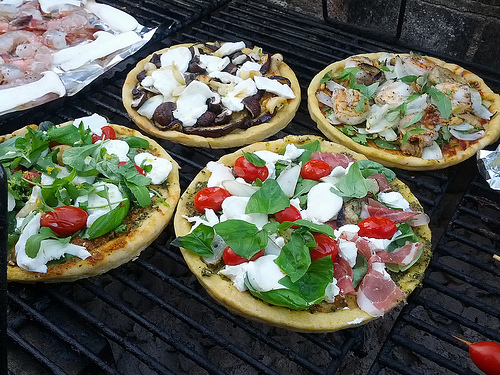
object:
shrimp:
[40, 29, 71, 50]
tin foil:
[0, 0, 159, 117]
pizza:
[306, 51, 500, 173]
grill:
[0, 0, 500, 375]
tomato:
[194, 186, 234, 214]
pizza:
[173, 134, 433, 334]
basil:
[213, 218, 270, 260]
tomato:
[234, 155, 270, 184]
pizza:
[121, 41, 303, 149]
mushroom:
[153, 101, 178, 126]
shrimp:
[331, 87, 370, 126]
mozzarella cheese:
[305, 181, 345, 223]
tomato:
[356, 216, 398, 240]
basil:
[245, 178, 291, 214]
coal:
[418, 286, 465, 325]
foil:
[475, 142, 500, 191]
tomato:
[300, 159, 331, 181]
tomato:
[274, 203, 303, 229]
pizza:
[0, 111, 182, 285]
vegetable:
[276, 253, 335, 302]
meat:
[332, 253, 355, 299]